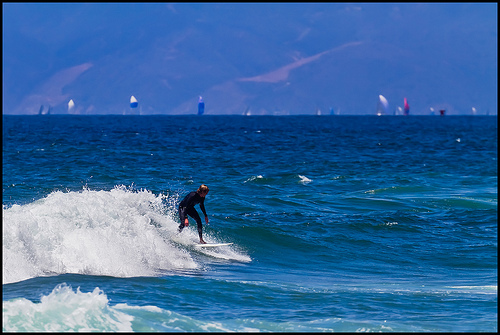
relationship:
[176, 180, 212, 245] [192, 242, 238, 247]
man on surfboard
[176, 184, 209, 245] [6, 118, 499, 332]
man on water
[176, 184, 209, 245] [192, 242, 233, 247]
man on surfboard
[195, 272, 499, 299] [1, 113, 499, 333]
line on ocean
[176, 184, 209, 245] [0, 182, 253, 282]
man rides wave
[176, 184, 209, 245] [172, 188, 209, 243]
man wearing wet suit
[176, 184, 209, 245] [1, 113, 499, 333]
man surfing in ocean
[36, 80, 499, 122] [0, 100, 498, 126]
boats seen on horizon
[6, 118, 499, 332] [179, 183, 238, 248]
water behind surfer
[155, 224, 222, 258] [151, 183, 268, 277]
legs on surfer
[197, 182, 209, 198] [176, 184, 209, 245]
head of man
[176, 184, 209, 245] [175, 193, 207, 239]
man wearing wet suit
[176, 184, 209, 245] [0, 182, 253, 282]
man riding wave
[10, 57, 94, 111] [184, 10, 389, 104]
cloud in sky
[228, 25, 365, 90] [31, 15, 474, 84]
cloud in sky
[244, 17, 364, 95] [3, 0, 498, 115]
white clouds in sky